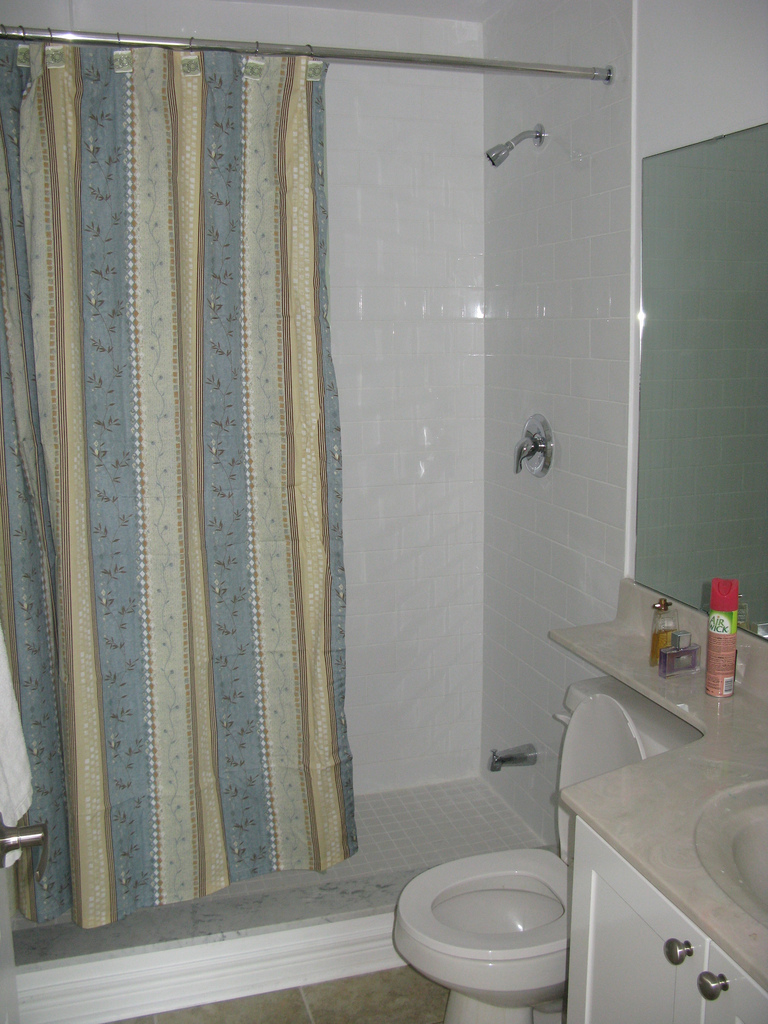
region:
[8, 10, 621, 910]
the shower is tiled in off white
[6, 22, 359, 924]
the shower curtain has stripes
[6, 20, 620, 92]
the shower curtain rod is chrome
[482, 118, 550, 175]
the showerhead and faucet are chrome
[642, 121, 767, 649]
a mirror is on the wall in the bathroom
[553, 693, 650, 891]
the toilet lid is in the upright position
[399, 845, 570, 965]
the toilet seat is down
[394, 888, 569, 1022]
the toilet bowl is white porcelain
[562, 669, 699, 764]
the water tank lid is in place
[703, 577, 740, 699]
an air freshening can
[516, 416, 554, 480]
a silver control for the water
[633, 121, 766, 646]
a mirror above a shelf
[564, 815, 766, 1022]
two doors with silver knobs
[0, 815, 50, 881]
silver door knob handles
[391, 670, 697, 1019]
a white colored porcelain toilet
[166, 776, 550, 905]
a tiled shower floor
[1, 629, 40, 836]
a towel hanging on the door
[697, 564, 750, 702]
air freshner on the counter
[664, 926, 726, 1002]
silver knob on the sink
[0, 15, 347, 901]
shower curtain hanging in the bathroom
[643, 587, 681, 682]
perfume on the counter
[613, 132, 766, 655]
mirror on the wall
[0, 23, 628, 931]
shower curtain hanging from silver rod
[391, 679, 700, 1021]
white toilet with an open lid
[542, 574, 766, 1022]
marble counter over white cabinets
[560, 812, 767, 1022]
silver handles on white cabinets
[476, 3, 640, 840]
silver shower head on white wall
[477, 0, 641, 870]
silver faucet on white wall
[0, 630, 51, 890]
white towel next to silver door handle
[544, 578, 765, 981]
perfume bottles on marble counter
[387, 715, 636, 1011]
the toilet is white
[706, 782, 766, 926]
the sink is white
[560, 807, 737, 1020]
the cabinet is white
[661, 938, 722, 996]
the knobs are silver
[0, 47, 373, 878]
the curtain has stripes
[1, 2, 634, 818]
the wall is tiled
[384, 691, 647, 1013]
the seat is up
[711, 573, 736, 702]
the bottle is red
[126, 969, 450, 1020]
the floor is beige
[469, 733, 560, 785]
silver facet in bathtub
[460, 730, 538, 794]
silver facet in bathtub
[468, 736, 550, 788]
silver facet in bathtub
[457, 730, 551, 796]
silver facet in bathtub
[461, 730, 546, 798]
silver facet in bathtub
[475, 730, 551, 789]
silver facet in bathtub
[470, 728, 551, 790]
silver facet in bathtub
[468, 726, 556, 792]
silver facet in bathtub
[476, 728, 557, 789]
silver facet in bathtub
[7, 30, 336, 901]
A blue and brown designed shower curtain.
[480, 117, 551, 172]
A silver shower head attached to the wall.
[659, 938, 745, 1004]
Silver knobs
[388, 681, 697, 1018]
A white toilet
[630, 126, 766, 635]
A large mirror on the wall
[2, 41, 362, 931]
material shower curtain hanging from rod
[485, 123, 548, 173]
standard shower head for showering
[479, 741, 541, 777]
water spigot for shower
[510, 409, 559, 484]
water control handle for shower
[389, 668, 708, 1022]
white porcelain toilet beside shower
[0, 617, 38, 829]
white terry towel for showering